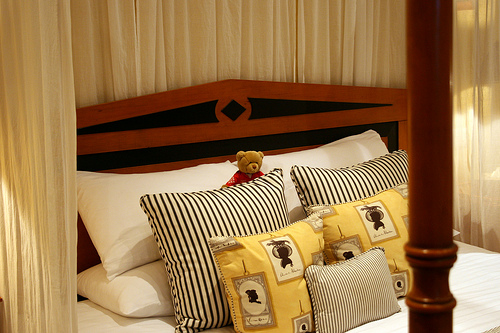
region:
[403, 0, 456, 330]
Brown column with four horizontal rings.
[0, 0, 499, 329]
Tan curtain around sides snd back of bed.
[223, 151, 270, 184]
Teddy bear behind a pillow edge.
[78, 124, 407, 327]
Five rows of pillows on this bed.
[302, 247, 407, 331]
One pillow has vertical stripes.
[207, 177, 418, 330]
Two pillows are yellow with patterns.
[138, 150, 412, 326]
Three pillows have black and white stripes.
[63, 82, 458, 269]
Post and headboard are made of wood.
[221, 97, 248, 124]
Black square on diagonal angle.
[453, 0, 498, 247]
Light is shining through the curtain.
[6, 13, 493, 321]
A made up bed in a bedroom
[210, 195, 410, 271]
The decorative pillows are yellow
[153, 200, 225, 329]
The decorative pillow is striped black and white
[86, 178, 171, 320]
The sleeping pillows on the bed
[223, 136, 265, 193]
The teddy bear on the bed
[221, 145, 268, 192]
The teddy bear is the color brown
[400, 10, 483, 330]
The bed post is made of wood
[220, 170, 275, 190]
The teddy bear is wearing a red shirt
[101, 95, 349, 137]
The design on the bed is white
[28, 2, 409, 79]
The bed curtains are the color white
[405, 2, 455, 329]
the red post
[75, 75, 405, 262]
the black and red headboard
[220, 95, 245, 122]
black diamond shape in middle of headboard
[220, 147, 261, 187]
a small teddy bear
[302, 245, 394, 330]
smallest striped pillow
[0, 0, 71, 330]
edge of a curtain on the left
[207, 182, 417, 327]
two yellow patterned pillows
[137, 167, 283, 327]
the striped pillow the teddy bear is behind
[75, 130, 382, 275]
top white pillows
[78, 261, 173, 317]
white pillow laying flat on the bed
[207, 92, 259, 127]
Black diamond on wood headboard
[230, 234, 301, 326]
Yellow throw pillow with black cameo design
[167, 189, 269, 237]
Large square throw pillow with black stripes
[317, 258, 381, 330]
Small rectangle throw pillow with black stripes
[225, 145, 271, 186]
Brown teddy bear behind pillow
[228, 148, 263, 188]
Brown stuff bear with red shirt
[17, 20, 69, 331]
Cream drapes surrounding bed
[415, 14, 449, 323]
Wooden post on canopy bed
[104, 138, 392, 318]
Group of nine pillows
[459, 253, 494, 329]
White sheet on bed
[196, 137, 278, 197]
teddy bear behind pillow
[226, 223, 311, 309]
yellow pillow with cat priny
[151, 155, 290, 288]
plack and white striped pillow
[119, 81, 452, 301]
wood frame and headboard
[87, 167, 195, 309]
fluffy white pillows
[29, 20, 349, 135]
curtain behind the bed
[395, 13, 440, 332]
wood bed post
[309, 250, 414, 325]
small striped pillow on bed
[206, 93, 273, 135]
black diamond design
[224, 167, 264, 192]
bear is wearing red coat